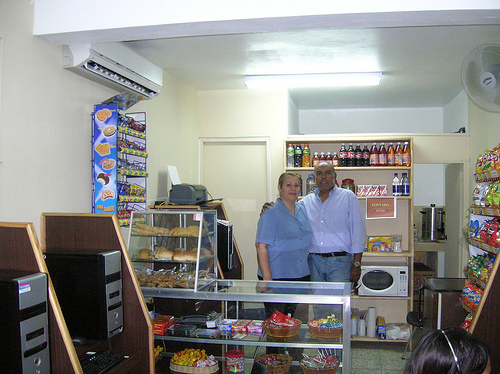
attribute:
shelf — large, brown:
[281, 134, 426, 362]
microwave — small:
[351, 258, 455, 310]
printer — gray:
[157, 150, 209, 210]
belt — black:
[317, 247, 345, 260]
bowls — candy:
[364, 311, 415, 349]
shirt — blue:
[257, 197, 313, 279]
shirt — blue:
[301, 192, 368, 254]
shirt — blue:
[245, 200, 335, 270]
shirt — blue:
[262, 203, 331, 292]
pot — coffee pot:
[427, 202, 443, 240]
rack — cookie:
[73, 93, 160, 221]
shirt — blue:
[297, 178, 371, 253]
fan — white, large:
[460, 46, 499, 114]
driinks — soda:
[288, 145, 413, 165]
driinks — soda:
[465, 152, 496, 298]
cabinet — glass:
[113, 270, 429, 369]